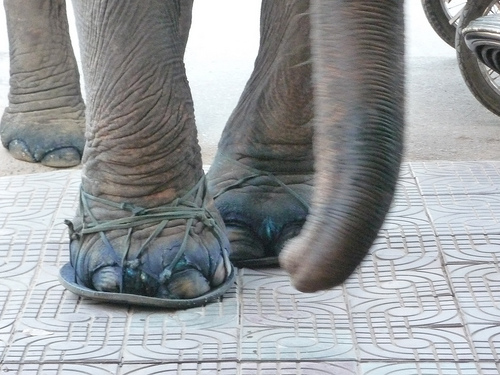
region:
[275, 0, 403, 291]
Trunk of big elephant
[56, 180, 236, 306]
Right front foot of elephant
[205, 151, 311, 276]
Left front foot of elephant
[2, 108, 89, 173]
Rear right foot of elephant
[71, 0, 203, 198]
Right front leg of elephant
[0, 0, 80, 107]
Rear right leg of elephant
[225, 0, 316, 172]
Elephant's left front leg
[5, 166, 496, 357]
Design tile elephant is standing on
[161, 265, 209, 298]
Middle toe of elephant's right foot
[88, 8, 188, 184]
Elephant's skin on right leg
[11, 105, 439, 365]
elephant wearing shoes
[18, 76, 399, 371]
elephant wearing shoes made with string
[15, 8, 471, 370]
an elephant on the sidewalk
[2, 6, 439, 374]
an elephant walking on a sidewalk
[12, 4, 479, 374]
an elephant walking outside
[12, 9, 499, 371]
an elephant walking on the sidewalk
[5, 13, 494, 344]
a sidewalk with an elephant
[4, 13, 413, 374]
a sidewalk with elephant shoes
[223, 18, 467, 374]
a large elephant trunk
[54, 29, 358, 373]
large elephant feet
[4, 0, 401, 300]
An elephant walking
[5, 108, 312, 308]
The feet of the elephant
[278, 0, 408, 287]
Part of the elephant's trunk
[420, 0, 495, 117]
Wheels for a type of transportation such as a bike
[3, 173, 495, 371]
Designs on the ground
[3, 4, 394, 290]
lines/wrinkles on the elephant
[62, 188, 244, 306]
The elephant has something strapped to its feet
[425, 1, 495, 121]
The wheels are black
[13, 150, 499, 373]
The designs on the ground are gray/silver looking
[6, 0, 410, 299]
The elephant looks brownish/grayish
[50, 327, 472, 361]
Geometric pattern on the floor.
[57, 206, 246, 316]
Elephant shoes with elephant feet.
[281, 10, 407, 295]
Elephant trunk hanging down.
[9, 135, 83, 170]
Elephant's large toenails.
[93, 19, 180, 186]
Wrinkled elephant gray skin on the knees.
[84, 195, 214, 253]
Strings tie elephant shoes.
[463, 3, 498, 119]
Silver metal object on the right.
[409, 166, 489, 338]
White tiles on the floor.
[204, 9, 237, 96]
White skies in the background.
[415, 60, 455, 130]
Water is visible on the right.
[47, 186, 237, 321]
a elephant feet with a shoe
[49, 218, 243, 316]
A shoe on the elephant foot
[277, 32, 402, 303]
A elephants trunk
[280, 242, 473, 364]
tiles under the elephants trunk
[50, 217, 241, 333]
tiles under the elephants feet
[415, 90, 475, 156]
A concrete side walk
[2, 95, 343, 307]
feet of a elephant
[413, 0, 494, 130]
Wheels beside the elephant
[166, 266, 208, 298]
toe nail on the elephants feet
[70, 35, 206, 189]
wrinkles on the elephants legs